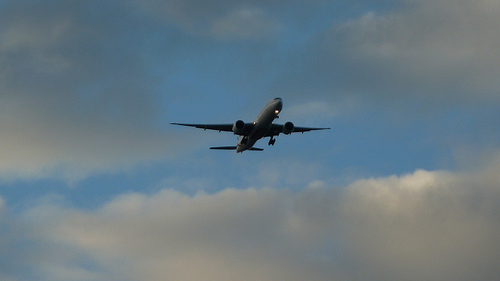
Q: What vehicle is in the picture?
A: Plane.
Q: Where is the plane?
A: In the sky.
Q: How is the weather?
A: Cloudy.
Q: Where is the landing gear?
A: Partially deployed.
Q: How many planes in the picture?
A: 1.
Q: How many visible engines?
A: 2.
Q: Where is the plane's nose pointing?
A: Top right corner.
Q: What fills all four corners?
A: Clouds.